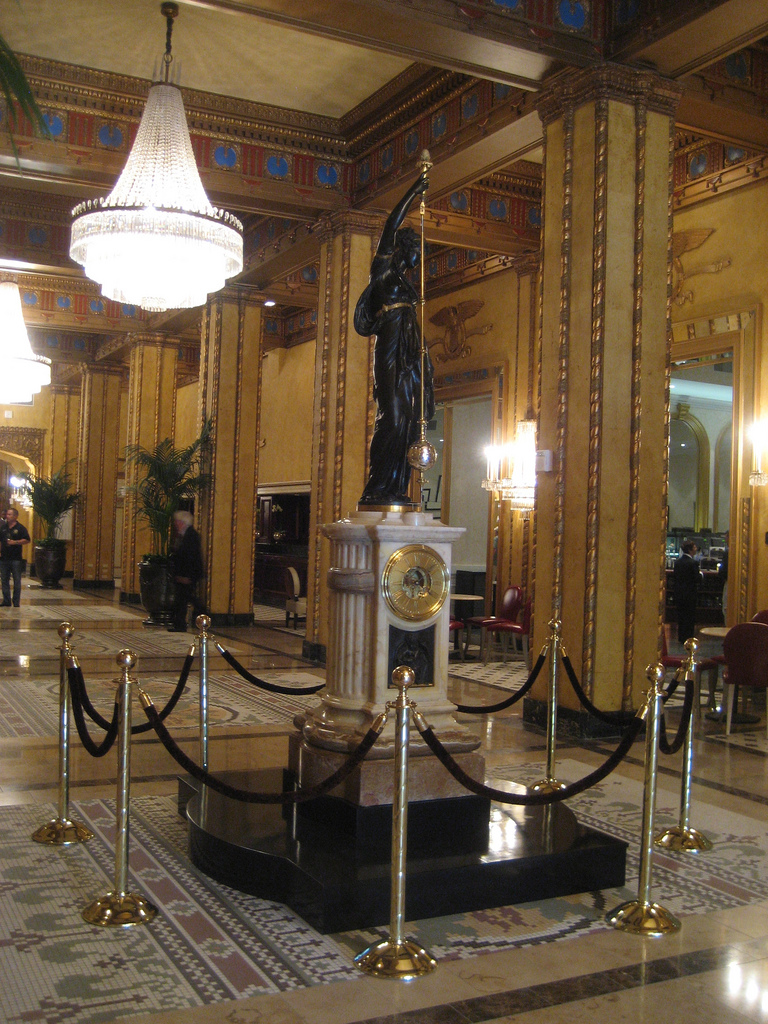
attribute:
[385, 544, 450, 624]
clock — gold 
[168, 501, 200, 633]
older man — grey haired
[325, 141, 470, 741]
statue — dark 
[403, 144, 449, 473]
rod —  golden 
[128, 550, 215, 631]
pot — brown 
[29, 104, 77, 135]
blue design — circular 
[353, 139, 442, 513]
statue — black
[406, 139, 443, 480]
rod — golden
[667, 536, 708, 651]
suited man — black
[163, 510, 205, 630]
man — grey haired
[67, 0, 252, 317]
chandelier — large 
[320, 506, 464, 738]
pedestal — black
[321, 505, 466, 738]
column — White 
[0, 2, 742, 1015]
room — large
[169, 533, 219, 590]
suit — black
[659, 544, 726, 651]
suit — black